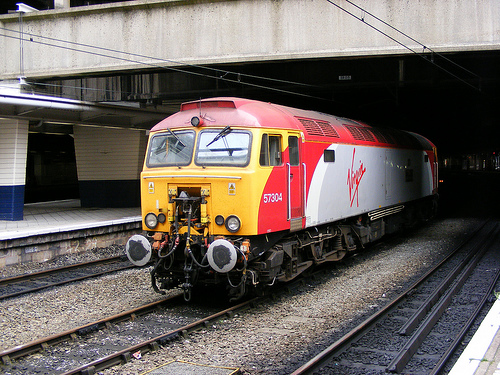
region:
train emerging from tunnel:
[45, 37, 491, 344]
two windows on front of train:
[125, 110, 270, 190]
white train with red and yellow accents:
[136, 107, 426, 237]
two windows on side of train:
[251, 125, 307, 167]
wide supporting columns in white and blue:
[5, 120, 140, 220]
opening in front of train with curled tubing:
[147, 181, 214, 266]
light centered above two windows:
[170, 106, 225, 152]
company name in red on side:
[336, 136, 386, 221]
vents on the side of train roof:
[295, 107, 395, 142]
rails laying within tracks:
[370, 210, 496, 357]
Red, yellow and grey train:
[121, 80, 468, 315]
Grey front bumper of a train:
[114, 220, 276, 309]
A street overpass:
[2, 2, 485, 231]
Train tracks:
[0, 275, 439, 374]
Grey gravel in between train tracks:
[177, 335, 277, 372]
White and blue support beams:
[1, 75, 132, 210]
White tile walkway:
[0, 193, 142, 252]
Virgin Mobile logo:
[333, 140, 384, 230]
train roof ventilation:
[279, 112, 420, 145]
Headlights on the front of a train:
[139, 200, 251, 235]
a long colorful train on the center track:
[121, 93, 443, 298]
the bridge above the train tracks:
[2, 0, 497, 77]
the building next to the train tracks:
[1, 75, 142, 225]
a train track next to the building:
[0, 257, 134, 301]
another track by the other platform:
[286, 200, 497, 372]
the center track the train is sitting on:
[1, 302, 227, 374]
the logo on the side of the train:
[346, 149, 364, 207]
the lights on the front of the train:
[144, 206, 244, 233]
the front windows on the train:
[145, 127, 257, 168]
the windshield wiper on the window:
[206, 130, 236, 152]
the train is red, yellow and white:
[123, 99, 457, 291]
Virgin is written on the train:
[345, 151, 364, 216]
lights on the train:
[138, 210, 275, 238]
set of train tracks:
[19, 296, 241, 373]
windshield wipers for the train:
[165, 123, 240, 146]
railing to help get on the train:
[280, 162, 315, 225]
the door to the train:
[277, 124, 323, 263]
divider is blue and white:
[8, 125, 38, 234]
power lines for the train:
[43, 41, 395, 107]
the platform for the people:
[18, 189, 132, 229]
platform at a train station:
[1, 190, 153, 242]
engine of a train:
[125, 91, 435, 294]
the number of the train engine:
[259, 190, 285, 207]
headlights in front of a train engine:
[143, 207, 242, 237]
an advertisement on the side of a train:
[338, 145, 370, 210]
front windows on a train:
[145, 128, 252, 170]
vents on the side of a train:
[297, 113, 378, 144]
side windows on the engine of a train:
[257, 130, 303, 169]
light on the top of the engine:
[188, 115, 200, 127]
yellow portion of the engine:
[134, 125, 309, 242]